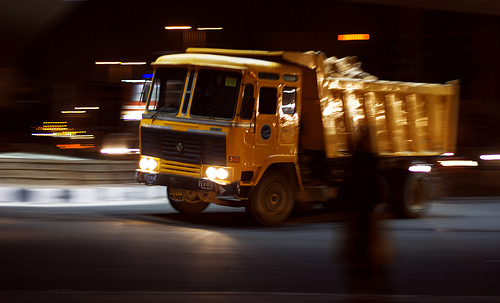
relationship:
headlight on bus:
[204, 165, 229, 181] [135, 48, 458, 226]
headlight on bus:
[134, 156, 158, 172] [135, 48, 458, 226]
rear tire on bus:
[392, 165, 434, 220] [135, 48, 458, 226]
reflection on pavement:
[175, 221, 245, 291] [8, 184, 483, 301]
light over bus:
[331, 26, 373, 50] [135, 48, 458, 226]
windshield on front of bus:
[147, 64, 242, 121] [135, 48, 458, 226]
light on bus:
[137, 156, 147, 171] [135, 48, 458, 226]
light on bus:
[139, 157, 157, 171] [135, 48, 458, 226]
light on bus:
[206, 166, 228, 178] [135, 48, 458, 226]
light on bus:
[206, 166, 228, 178] [136, 33, 468, 220]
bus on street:
[135, 48, 458, 226] [0, 195, 498, 300]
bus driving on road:
[135, 48, 458, 226] [1, 193, 496, 300]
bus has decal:
[135, 48, 458, 226] [258, 120, 273, 140]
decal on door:
[258, 125, 272, 140] [253, 81, 278, 146]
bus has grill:
[135, 48, 458, 226] [141, 125, 223, 165]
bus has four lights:
[135, 48, 458, 226] [146, 152, 268, 209]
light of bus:
[139, 157, 157, 171] [135, 48, 458, 226]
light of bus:
[206, 166, 228, 178] [135, 48, 458, 226]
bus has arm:
[135, 48, 458, 226] [243, 67, 256, 134]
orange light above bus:
[338, 30, 373, 42] [135, 48, 458, 226]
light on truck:
[206, 165, 227, 183] [123, 25, 485, 259]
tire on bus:
[247, 170, 295, 227] [135, 48, 458, 226]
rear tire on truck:
[392, 165, 434, 219] [136, 47, 461, 217]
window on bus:
[192, 65, 248, 137] [135, 48, 458, 226]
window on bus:
[146, 71, 181, 112] [135, 48, 458, 226]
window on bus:
[280, 83, 299, 115] [135, 48, 458, 226]